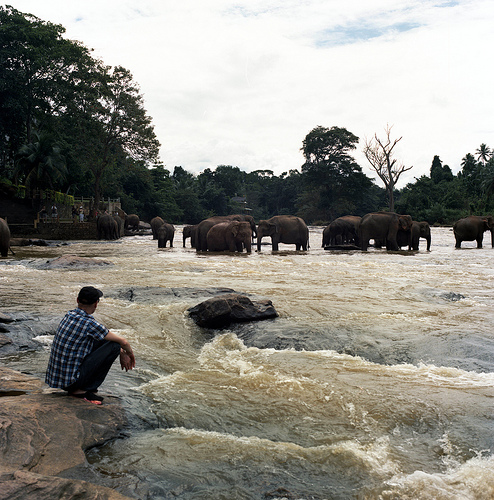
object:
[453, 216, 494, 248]
elephants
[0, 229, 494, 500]
water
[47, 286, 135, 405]
man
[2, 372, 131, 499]
rock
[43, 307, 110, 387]
shirt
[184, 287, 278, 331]
rock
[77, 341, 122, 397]
pants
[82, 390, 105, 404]
shoes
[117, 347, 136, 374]
hands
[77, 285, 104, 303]
cap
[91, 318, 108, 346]
short sleeves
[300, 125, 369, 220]
trees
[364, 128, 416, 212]
tree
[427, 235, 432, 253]
trunk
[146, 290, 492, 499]
rapids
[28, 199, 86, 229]
people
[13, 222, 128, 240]
ledge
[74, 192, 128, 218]
fence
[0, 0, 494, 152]
sky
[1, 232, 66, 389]
rocks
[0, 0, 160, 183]
leaves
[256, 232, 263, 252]
trunk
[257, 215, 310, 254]
elephant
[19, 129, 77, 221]
tree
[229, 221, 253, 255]
head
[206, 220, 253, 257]
elephant